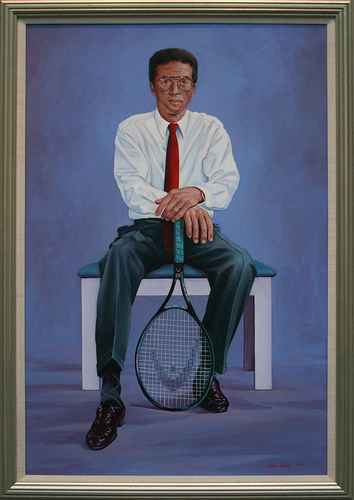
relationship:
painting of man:
[4, 7, 345, 268] [83, 46, 257, 449]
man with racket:
[83, 46, 257, 449] [140, 202, 222, 419]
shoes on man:
[79, 373, 220, 449] [86, 39, 241, 445]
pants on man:
[95, 217, 256, 374] [83, 46, 257, 449]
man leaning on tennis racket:
[83, 46, 257, 449] [132, 207, 221, 427]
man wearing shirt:
[83, 46, 257, 449] [113, 107, 241, 220]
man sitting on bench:
[83, 46, 257, 449] [66, 212, 287, 402]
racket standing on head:
[127, 217, 214, 407] [135, 308, 214, 410]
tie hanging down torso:
[163, 124, 180, 255] [113, 109, 240, 218]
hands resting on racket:
[145, 187, 221, 243] [126, 205, 216, 410]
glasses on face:
[124, 57, 238, 107] [156, 63, 193, 113]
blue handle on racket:
[173, 214, 184, 262] [126, 205, 216, 410]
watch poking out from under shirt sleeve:
[199, 189, 205, 200] [194, 118, 241, 209]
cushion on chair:
[75, 250, 276, 277] [75, 275, 278, 392]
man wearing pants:
[83, 46, 257, 449] [94, 224, 150, 279]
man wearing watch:
[83, 46, 257, 449] [193, 183, 204, 201]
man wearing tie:
[83, 46, 257, 449] [166, 123, 179, 198]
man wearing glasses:
[83, 46, 257, 449] [148, 75, 195, 92]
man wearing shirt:
[83, 46, 257, 449] [110, 103, 243, 220]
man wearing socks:
[73, 40, 261, 456] [82, 352, 137, 415]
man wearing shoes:
[83, 46, 257, 449] [86, 401, 132, 448]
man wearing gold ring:
[73, 40, 261, 456] [173, 200, 185, 211]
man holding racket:
[83, 46, 257, 449] [134, 219, 215, 412]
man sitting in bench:
[83, 46, 257, 449] [76, 260, 277, 391]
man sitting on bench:
[83, 46, 257, 449] [76, 252, 277, 390]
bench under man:
[76, 270, 278, 393] [83, 46, 257, 449]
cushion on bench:
[77, 250, 277, 279] [76, 252, 277, 390]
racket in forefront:
[134, 219, 215, 412] [24, 192, 327, 474]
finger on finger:
[161, 201, 176, 221] [163, 201, 185, 222]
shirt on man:
[110, 103, 243, 220] [83, 46, 257, 449]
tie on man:
[150, 128, 208, 198] [61, 40, 316, 275]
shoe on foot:
[84, 397, 126, 450] [74, 394, 137, 455]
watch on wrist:
[195, 186, 207, 204] [187, 183, 211, 204]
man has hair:
[83, 46, 257, 449] [138, 37, 217, 65]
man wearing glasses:
[73, 40, 261, 456] [154, 72, 194, 92]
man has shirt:
[83, 46, 257, 449] [110, 103, 243, 220]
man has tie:
[83, 46, 257, 449] [164, 122, 180, 258]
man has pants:
[83, 46, 257, 449] [95, 215, 253, 375]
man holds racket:
[83, 46, 257, 449] [126, 205, 216, 410]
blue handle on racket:
[173, 219, 184, 262] [131, 203, 219, 407]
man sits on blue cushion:
[83, 46, 257, 449] [75, 255, 277, 278]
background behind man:
[27, 27, 314, 387] [115, 38, 243, 229]